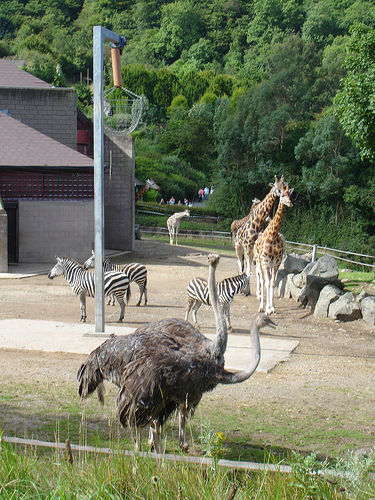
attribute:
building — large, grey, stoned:
[1, 49, 137, 270]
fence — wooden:
[131, 225, 372, 267]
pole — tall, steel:
[87, 19, 114, 339]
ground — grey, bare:
[1, 240, 374, 495]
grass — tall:
[1, 376, 374, 497]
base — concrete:
[1, 312, 301, 379]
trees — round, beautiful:
[1, 1, 372, 264]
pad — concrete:
[1, 318, 298, 360]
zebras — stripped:
[44, 242, 149, 327]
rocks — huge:
[281, 248, 373, 325]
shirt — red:
[195, 189, 205, 198]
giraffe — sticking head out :
[133, 178, 153, 205]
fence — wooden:
[7, 431, 372, 499]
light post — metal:
[86, 16, 115, 332]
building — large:
[0, 38, 145, 267]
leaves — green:
[238, 37, 285, 83]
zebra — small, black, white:
[180, 270, 255, 329]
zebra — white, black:
[41, 252, 137, 321]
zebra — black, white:
[82, 245, 152, 309]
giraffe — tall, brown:
[246, 183, 296, 324]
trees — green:
[212, 11, 351, 192]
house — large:
[2, 52, 158, 266]